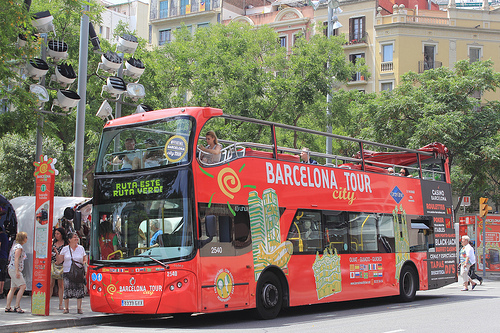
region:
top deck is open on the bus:
[159, 82, 467, 209]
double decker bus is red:
[177, 142, 494, 307]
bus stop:
[31, 136, 60, 332]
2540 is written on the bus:
[203, 240, 227, 259]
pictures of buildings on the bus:
[221, 190, 443, 292]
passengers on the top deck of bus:
[122, 136, 249, 177]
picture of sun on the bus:
[198, 155, 272, 217]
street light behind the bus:
[476, 188, 496, 263]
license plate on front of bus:
[110, 291, 182, 316]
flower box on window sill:
[332, 34, 380, 56]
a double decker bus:
[62, 97, 462, 298]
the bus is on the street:
[32, 79, 482, 330]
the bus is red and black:
[79, 106, 457, 302]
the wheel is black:
[237, 262, 298, 327]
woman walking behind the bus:
[457, 223, 485, 294]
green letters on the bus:
[92, 174, 170, 195]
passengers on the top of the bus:
[105, 117, 432, 178]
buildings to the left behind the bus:
[208, 0, 498, 167]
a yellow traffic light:
[476, 191, 491, 276]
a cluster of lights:
[7, 7, 154, 104]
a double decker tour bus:
[90, 117, 460, 313]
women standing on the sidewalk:
[47, 226, 86, 317]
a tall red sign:
[30, 154, 55, 314]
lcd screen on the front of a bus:
[106, 179, 164, 196]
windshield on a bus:
[90, 199, 190, 263]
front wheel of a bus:
[255, 269, 282, 319]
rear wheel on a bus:
[399, 261, 419, 300]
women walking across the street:
[457, 236, 481, 292]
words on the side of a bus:
[262, 161, 374, 201]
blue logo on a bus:
[387, 186, 404, 201]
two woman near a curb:
[53, 225, 90, 313]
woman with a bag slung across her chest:
[57, 231, 91, 314]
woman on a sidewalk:
[2, 233, 34, 316]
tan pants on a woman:
[5, 261, 27, 290]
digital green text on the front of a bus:
[88, 173, 183, 198]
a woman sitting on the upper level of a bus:
[194, 133, 226, 163]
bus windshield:
[93, 202, 190, 263]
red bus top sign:
[30, 153, 60, 318]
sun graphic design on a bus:
[196, 158, 258, 223]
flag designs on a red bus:
[344, 259, 390, 281]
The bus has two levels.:
[95, 115, 472, 311]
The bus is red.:
[95, 107, 467, 311]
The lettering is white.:
[260, 158, 376, 195]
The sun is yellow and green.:
[199, 161, 251, 209]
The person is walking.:
[457, 236, 479, 290]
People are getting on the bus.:
[55, 209, 99, 304]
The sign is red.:
[29, 154, 52, 315]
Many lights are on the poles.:
[24, 11, 161, 128]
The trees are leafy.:
[142, 32, 484, 157]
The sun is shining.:
[3, 6, 497, 331]